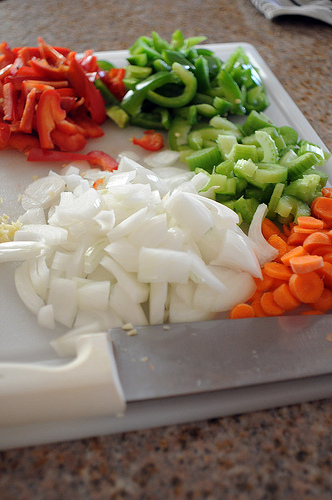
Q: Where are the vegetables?
A: Cutting board.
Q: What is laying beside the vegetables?
A: Knife.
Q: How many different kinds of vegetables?
A: Five.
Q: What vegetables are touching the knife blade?
A: Carrots and onions.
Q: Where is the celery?
A: Beside the carrots.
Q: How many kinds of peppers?
A: Two.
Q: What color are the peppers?
A: Red and green.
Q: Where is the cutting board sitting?
A: Countertop.